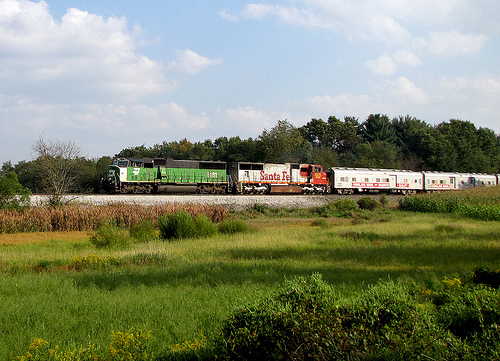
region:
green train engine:
[92, 149, 229, 192]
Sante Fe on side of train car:
[254, 169, 297, 184]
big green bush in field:
[148, 207, 215, 241]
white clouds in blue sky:
[1, 6, 498, 121]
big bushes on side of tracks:
[22, 132, 89, 216]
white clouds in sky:
[0, 8, 216, 122]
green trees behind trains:
[31, 111, 498, 193]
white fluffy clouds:
[336, 69, 498, 113]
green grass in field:
[11, 207, 498, 350]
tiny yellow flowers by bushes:
[22, 317, 221, 358]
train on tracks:
[105, 153, 480, 200]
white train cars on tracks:
[332, 162, 482, 185]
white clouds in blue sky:
[22, 31, 89, 71]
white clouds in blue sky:
[167, 45, 228, 82]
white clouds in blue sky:
[262, 36, 317, 73]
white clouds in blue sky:
[360, 54, 422, 94]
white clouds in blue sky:
[87, 54, 139, 84]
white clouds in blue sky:
[10, 76, 72, 103]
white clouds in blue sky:
[147, 48, 191, 83]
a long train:
[101, 157, 498, 193]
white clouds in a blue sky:
[1, 0, 497, 167]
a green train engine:
[101, 156, 230, 191]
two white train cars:
[331, 167, 499, 194]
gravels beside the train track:
[0, 190, 404, 206]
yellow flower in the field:
[20, 330, 212, 359]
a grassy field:
[1, 218, 494, 357]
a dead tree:
[31, 132, 78, 205]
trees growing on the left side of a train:
[1, 113, 498, 193]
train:
[93, 147, 490, 211]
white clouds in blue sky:
[15, 26, 56, 66]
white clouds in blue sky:
[274, 66, 321, 104]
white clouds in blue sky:
[73, 31, 146, 78]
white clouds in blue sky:
[240, 12, 290, 83]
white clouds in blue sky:
[80, 89, 133, 121]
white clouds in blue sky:
[175, 55, 223, 94]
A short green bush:
[232, 280, 359, 357]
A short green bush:
[349, 260, 444, 357]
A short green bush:
[440, 259, 499, 351]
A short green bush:
[29, 316, 184, 358]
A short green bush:
[157, 200, 216, 237]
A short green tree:
[439, 113, 499, 162]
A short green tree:
[392, 93, 445, 169]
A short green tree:
[311, 97, 391, 159]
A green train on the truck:
[104, 145, 229, 190]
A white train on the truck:
[234, 157, 335, 197]